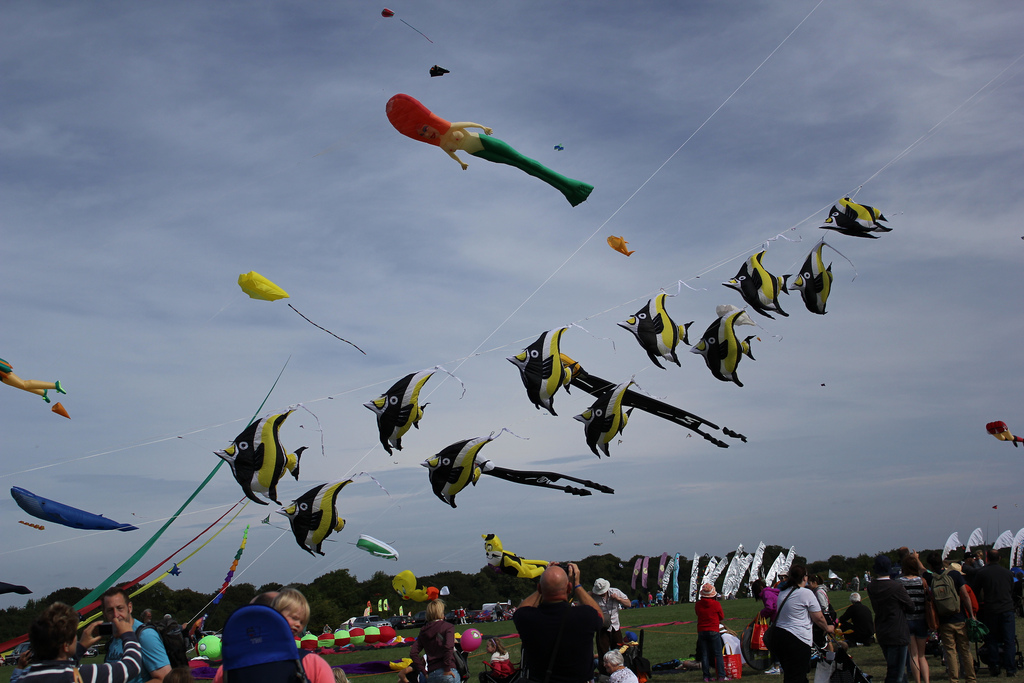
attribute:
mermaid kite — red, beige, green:
[382, 96, 588, 231]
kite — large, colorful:
[382, 82, 584, 216]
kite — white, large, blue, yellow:
[818, 182, 892, 247]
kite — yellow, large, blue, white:
[231, 415, 314, 500]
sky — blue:
[2, 1, 1018, 581]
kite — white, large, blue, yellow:
[276, 472, 365, 559]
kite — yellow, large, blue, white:
[365, 378, 439, 454]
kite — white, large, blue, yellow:
[417, 426, 601, 522]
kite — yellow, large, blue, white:
[507, 333, 747, 461]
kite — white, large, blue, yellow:
[572, 381, 652, 455]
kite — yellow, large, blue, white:
[619, 286, 713, 369]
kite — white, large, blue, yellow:
[695, 303, 769, 397]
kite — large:
[236, 267, 373, 360]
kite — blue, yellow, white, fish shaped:
[215, 405, 311, 511]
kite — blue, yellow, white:
[253, 472, 366, 565]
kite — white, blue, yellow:
[357, 363, 451, 467]